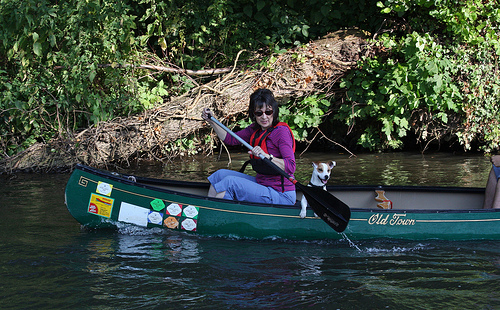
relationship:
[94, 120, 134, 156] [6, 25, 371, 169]
bark of a tree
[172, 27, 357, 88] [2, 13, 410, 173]
bark of a tree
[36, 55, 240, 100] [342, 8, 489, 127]
branch of a tree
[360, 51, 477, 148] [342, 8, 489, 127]
branch of a tree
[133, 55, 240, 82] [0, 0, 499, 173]
branch of a fallen tree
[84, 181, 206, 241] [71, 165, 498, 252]
stickers on canoe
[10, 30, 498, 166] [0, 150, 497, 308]
fallen tree in river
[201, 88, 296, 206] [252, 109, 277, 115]
person wearing sunglasses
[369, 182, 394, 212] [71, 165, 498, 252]
seat in canoe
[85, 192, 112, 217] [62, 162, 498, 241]
sticker on canoe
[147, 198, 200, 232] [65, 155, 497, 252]
sticker on canoe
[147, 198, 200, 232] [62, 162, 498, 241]
sticker on canoe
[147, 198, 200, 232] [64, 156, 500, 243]
sticker on boat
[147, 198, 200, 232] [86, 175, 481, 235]
sticker on canoe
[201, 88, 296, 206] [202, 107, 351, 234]
person using paddle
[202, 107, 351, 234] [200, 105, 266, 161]
paddle has handle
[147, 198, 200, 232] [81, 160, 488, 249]
sticker stuck on canoe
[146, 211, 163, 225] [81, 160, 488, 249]
sticker stuck on canoe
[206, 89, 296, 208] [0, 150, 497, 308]
person canoeing in river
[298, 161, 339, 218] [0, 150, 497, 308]
animal canoeing in river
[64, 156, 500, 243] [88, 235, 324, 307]
boat casting reflection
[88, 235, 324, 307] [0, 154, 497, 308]
reflection on water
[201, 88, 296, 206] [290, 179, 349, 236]
person paddling with black oar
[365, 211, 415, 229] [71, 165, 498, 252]
old town written on canoe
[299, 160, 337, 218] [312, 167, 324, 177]
animal has eye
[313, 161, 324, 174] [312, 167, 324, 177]
brown patch over eye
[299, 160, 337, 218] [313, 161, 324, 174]
animal has brown patch